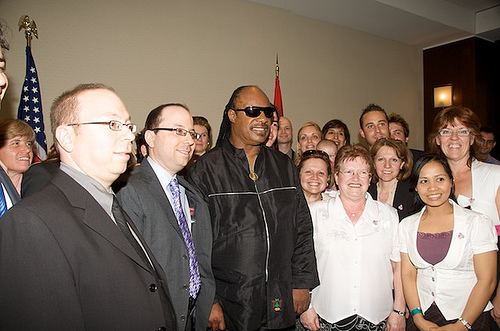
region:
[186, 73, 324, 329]
Stevie wonder with other people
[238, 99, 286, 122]
dark glasses on face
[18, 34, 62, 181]
the american flag on pole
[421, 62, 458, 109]
a light on the wall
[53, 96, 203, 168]
two men in regular glasses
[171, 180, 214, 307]
a purple neck tie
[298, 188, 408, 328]
white blouse and black shirt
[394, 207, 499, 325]
a purple shirt with white over top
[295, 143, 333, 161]
sunglasses on top of woman's head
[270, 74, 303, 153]
a part of a red flag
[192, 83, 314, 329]
black man with sunglasses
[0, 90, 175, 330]
white man in a grey suit and dark tie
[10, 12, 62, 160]
American flag in background of group photo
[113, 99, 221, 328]
white man in a grey suit with blue and white tie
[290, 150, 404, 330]
short woman with glasses in a white shirt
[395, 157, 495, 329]
black woman with a purple shirt and white shirt over it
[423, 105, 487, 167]
taller woman with reddish hair and glasses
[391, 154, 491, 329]
woman holding her hands together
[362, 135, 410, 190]
woman in a dark suit and reddish blond hair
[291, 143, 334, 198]
shorter woman peeking between black man and white woman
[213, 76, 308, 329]
stevie wonder with a group of people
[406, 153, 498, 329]
woman with white shirt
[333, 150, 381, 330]
woman with white shirt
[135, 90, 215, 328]
guy wearing a purple tie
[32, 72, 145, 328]
guy wearing a suit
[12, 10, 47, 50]
eagle on the top of the flag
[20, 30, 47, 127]
stars on the american flag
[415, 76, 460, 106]
light in back of the people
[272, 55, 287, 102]
red tipped flag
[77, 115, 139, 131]
glasses on the guy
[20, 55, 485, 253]
many people in a room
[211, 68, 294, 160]
head of a man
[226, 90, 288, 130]
sunglasses on man's face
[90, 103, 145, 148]
glasses on man's face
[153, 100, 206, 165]
head of a man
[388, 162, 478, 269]
woman with a white and purple outfit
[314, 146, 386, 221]
woman with glasses on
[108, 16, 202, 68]
wall in the background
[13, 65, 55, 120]
stars on the flag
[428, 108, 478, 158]
woman looking at the camera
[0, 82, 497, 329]
a group of smiling people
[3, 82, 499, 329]
black man surrounded by white people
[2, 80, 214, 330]
two men in suits wearing glasses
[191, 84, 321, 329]
black man wearing sunglasses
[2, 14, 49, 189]
American flag behind smiling woman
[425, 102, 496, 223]
tall red-haired woman wearing glasses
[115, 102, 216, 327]
man wearing gray suit and purple tie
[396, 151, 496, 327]
woman wearing a bracelet on each wrist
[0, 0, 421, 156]
two flags in front of white wall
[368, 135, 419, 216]
woman wearing tan shirt and black blazer